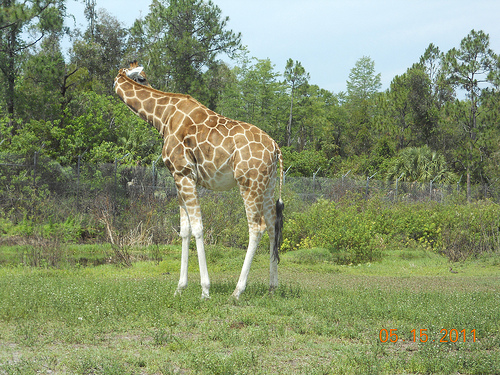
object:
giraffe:
[111, 59, 286, 302]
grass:
[1, 233, 499, 374]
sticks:
[94, 199, 126, 261]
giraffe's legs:
[226, 156, 266, 301]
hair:
[268, 199, 285, 264]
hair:
[118, 59, 190, 101]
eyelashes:
[136, 77, 149, 83]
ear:
[126, 66, 144, 81]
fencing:
[2, 149, 495, 215]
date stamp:
[375, 324, 479, 343]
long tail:
[269, 149, 288, 269]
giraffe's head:
[121, 58, 155, 90]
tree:
[443, 30, 499, 203]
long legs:
[168, 152, 210, 305]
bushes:
[1, 198, 499, 267]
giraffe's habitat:
[1, 1, 500, 373]